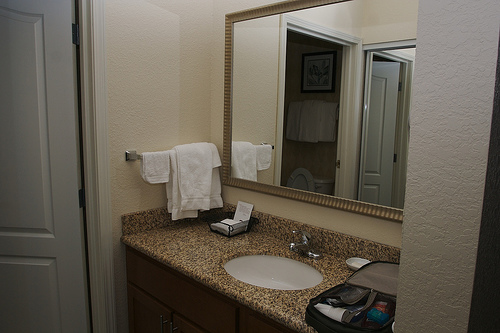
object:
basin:
[220, 251, 323, 290]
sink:
[218, 250, 326, 290]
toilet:
[286, 167, 333, 195]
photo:
[0, 0, 499, 333]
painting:
[299, 51, 337, 94]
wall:
[88, 0, 498, 333]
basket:
[207, 201, 259, 238]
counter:
[118, 221, 387, 332]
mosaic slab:
[150, 225, 217, 262]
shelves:
[123, 242, 299, 332]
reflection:
[229, 0, 418, 209]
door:
[358, 62, 401, 209]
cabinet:
[127, 244, 301, 333]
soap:
[351, 262, 365, 268]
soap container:
[346, 257, 372, 271]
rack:
[289, 99, 338, 108]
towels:
[286, 100, 337, 143]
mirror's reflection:
[229, 1, 418, 210]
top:
[122, 227, 400, 333]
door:
[0, 0, 85, 333]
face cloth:
[141, 152, 170, 184]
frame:
[205, 5, 320, 13]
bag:
[304, 261, 402, 332]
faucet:
[288, 231, 323, 260]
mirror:
[230, 0, 417, 210]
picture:
[299, 48, 339, 94]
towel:
[140, 142, 223, 220]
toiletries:
[321, 272, 386, 330]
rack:
[125, 150, 143, 161]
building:
[0, 0, 500, 333]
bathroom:
[0, 0, 500, 330]